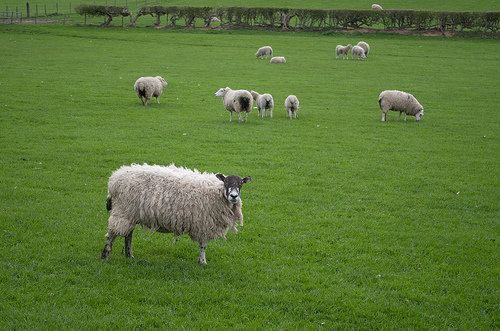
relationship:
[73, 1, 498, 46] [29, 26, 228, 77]
trees dividing field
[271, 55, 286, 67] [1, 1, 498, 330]
sheep laying on green field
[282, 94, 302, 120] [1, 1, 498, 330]
sheep in green field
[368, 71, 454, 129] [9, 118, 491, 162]
sheep eating grass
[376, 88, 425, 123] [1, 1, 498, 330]
sheep on green field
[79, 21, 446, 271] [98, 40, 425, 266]
herd of sheep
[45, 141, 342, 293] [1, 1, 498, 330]
sheep in green field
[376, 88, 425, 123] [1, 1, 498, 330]
sheep in green field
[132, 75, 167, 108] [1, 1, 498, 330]
gray sheep in green field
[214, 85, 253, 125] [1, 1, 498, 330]
sheep in green field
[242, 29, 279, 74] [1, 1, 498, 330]
sheep in green field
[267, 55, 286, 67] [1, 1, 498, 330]
sheep in green field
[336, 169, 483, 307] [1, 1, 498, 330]
grass in green field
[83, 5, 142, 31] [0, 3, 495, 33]
plants along fence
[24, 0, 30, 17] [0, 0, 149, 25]
pole on fence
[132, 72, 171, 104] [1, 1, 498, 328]
gray sheep in green field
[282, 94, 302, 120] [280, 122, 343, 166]
sheep eating grass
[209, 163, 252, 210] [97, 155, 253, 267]
head of a sheep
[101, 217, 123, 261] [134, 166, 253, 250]
leg of a sheep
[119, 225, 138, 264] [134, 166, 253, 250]
leg of a sheep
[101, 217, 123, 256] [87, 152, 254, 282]
leg of a sheep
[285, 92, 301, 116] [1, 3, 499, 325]
sheep standing on grass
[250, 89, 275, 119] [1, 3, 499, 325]
sheep standing on grass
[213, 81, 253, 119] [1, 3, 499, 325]
sheep standing on grass